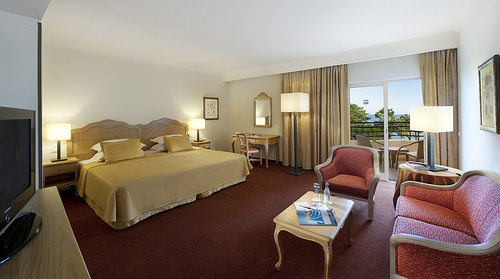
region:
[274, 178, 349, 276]
tan colored coffee table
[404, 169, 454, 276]
pink and gray small couch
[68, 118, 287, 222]
mustard yellow bed spread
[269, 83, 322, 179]
tall sqaure lamp shade floor lamp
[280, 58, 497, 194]
gold floral spread out curtains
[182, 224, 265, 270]
burgandy colored rug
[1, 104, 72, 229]
black flat screen on table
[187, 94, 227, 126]
floral art frame on wall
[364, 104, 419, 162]
french doors with deck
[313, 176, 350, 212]
water bottle and glass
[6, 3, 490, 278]
a well-lit bedroom scene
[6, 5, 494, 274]
a clean and nice hotel room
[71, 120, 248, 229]
a bed with tan covers and a wood headboard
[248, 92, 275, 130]
hanging mirror with a wood frame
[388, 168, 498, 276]
couch with red upholstery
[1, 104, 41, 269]
black television on a wood stand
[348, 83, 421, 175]
sliding glass doors looking out to a balcony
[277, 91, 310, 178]
floor lamp with square lampshade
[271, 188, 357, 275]
wood coffee table with water bottles on it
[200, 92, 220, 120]
picture hanging on the wall with a wood frame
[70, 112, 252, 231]
Large bed next to nightstand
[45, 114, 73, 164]
Lamp above wooden nightstand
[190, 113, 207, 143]
Lamp above wooden nightstand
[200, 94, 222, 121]
Artwork hung on wall near lamp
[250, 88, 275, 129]
Mirror above wooden desk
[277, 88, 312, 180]
Large floor lamp in front of beige curtain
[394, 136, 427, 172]
Wicker chair in balcony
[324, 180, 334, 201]
Plastic bottle on table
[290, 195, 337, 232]
Magazine on wooden table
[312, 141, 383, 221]
Red sofa chair next to lamp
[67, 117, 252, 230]
A large bed with creme colored blankets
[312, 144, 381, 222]
A red and white padded chair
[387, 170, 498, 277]
A red and white love seat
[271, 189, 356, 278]
A wooden coffee table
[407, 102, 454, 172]
A black lamp with a white lampshade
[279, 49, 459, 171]
Floor to ceiling curtains covering a balcony door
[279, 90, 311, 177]
A black floor lamp with a white lampshade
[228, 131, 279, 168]
A wooden desk and chair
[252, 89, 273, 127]
A wooden framed mirror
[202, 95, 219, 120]
A wall hung picture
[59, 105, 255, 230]
completely made up bed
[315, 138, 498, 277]
red and grey couch and chair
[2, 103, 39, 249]
flatscreen television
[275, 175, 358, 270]
white coffee table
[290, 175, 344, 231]
water bottles and magazine on coffee table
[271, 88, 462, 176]
two lit up lamps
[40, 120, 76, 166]
lamp on bedside table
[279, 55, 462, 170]
long beige drapes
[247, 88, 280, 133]
ornate mirror on wall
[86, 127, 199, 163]
propped up pillows on bed